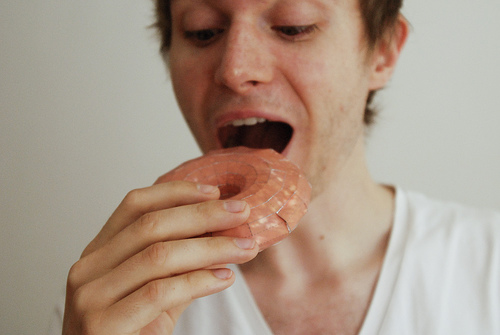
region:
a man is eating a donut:
[47, 19, 499, 314]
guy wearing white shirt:
[133, 79, 423, 320]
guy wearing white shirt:
[160, 148, 355, 308]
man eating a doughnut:
[35, 0, 498, 333]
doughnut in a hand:
[137, 131, 317, 253]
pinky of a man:
[130, 266, 252, 290]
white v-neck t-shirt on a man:
[376, 181, 496, 333]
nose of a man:
[211, 30, 271, 92]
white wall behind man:
[9, 4, 132, 183]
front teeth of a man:
[229, 118, 261, 128]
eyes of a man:
[167, 3, 332, 49]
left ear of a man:
[368, 8, 417, 97]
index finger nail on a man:
[194, 177, 224, 207]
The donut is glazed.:
[144, 140, 313, 255]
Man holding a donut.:
[64, 130, 311, 333]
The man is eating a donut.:
[164, 96, 314, 236]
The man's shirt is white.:
[11, 181, 498, 328]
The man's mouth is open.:
[205, 104, 299, 173]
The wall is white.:
[1, 2, 498, 334]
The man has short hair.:
[140, 1, 407, 143]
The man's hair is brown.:
[142, 2, 413, 129]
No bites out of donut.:
[141, 135, 308, 251]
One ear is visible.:
[355, 10, 414, 98]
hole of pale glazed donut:
[199, 172, 253, 209]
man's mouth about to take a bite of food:
[201, 109, 302, 167]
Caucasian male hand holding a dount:
[39, 145, 314, 331]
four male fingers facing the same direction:
[58, 176, 259, 331]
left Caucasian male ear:
[365, 10, 410, 97]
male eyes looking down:
[156, 5, 333, 47]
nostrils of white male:
[210, 70, 280, 95]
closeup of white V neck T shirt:
[233, 269, 394, 331]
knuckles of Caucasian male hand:
[63, 236, 103, 334]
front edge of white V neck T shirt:
[367, 171, 409, 332]